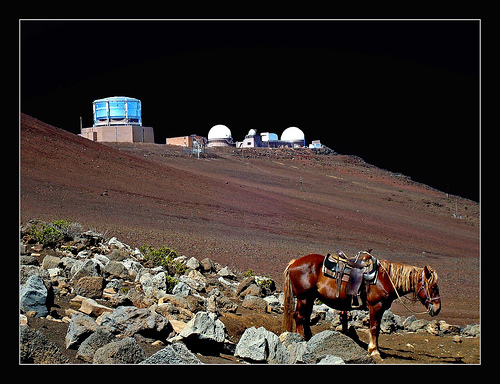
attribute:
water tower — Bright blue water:
[93, 96, 142, 121]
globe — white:
[90, 96, 146, 120]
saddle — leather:
[320, 245, 380, 322]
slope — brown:
[15, 112, 482, 317]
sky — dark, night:
[21, 22, 482, 114]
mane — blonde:
[386, 253, 438, 288]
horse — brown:
[272, 232, 460, 361]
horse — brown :
[280, 249, 443, 364]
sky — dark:
[219, 59, 418, 166]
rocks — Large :
[235, 321, 375, 363]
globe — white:
[205, 123, 232, 140]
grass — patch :
[31, 217, 68, 242]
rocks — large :
[21, 235, 232, 340]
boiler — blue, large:
[92, 91, 143, 125]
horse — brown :
[273, 227, 448, 337]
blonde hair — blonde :
[365, 246, 432, 287]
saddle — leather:
[310, 246, 380, 298]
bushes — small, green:
[149, 246, 168, 265]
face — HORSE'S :
[403, 243, 479, 333]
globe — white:
[278, 121, 308, 143]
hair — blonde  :
[276, 256, 297, 336]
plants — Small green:
[29, 215, 71, 245]